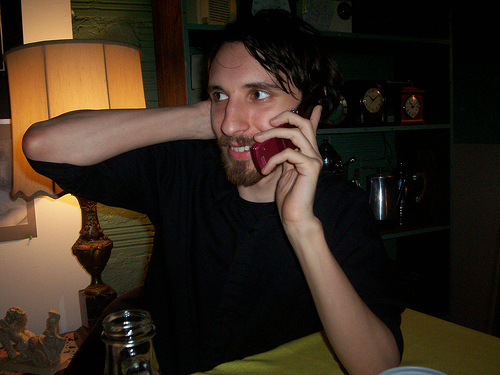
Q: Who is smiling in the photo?
A: The man.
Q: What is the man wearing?
A: A shirt.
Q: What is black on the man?
A: The shirt.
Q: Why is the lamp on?
A: To bring light into the room.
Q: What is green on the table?
A: The table cloth.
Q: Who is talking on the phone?
A: The man.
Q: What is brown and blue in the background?
A: The bookshelf.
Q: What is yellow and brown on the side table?
A: The lamp.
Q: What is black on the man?
A: The shirt.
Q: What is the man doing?
A: Talking on the telephone.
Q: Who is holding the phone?
A: A man with a beard.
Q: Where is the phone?
A: Next to the man's ear.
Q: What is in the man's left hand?
A: Red cell phone.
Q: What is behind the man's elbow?
A: A lamp.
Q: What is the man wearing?
A: Black shirt.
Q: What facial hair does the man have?
A: A beard.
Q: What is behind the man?
A: Green shelf.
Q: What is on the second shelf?
A: Coffee pots.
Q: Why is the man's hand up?
A: Holding the phone.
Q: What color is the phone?
A: Red.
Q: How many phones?
A: 1.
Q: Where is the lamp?
A: Behind the man.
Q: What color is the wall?
A: White.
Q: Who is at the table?
A: The man.